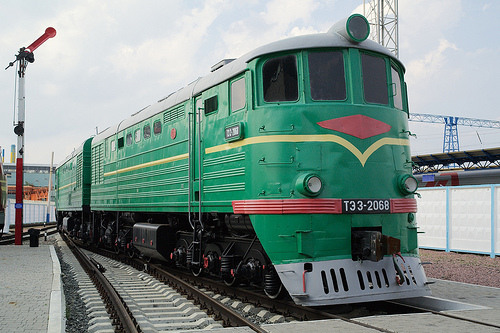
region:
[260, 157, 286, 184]
thetrain is green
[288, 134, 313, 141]
the train is yellow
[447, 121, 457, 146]
the tower is blue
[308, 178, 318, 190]
the light is off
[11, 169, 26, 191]
the pole is red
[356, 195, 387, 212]
the numbers are white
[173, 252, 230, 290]
the train is on the track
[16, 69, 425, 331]
the train is green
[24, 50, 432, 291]
the train is green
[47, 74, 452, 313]
the train is green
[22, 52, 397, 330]
the train is green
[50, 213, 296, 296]
train's wheels are black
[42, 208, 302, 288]
train's wheels are black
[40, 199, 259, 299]
train's wheels are black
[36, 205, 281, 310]
train's wheels are black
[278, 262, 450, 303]
The grill of the train.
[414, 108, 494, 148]
A crane sits in the background.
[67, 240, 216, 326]
An empty rail track.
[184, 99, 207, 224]
The door into the train.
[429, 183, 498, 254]
A wall enclosure.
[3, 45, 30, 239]
A light pole.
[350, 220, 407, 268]
The train spot light.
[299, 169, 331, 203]
right head light of a train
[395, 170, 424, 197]
left head light of a train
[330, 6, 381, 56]
head light on top of a train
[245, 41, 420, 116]
front window of a train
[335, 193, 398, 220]
License plate on front of a train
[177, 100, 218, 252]
Ladder rails on side of train door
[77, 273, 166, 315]
Metal train tracks on gravel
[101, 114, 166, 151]
Windows on the side of a train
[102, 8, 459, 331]
Green train on train tracks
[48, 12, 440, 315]
green passenger train on track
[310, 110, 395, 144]
red spot on front of train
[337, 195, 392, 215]
identification number on front of train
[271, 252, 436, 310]
gray metal grate on train front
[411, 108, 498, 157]
blue construction crane in background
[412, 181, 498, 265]
blue and white divider wall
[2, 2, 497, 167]
fluffy white clouds in sky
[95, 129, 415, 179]
yellow stripe on train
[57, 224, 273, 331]
left side train track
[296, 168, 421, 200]
headlights on front of train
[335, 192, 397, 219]
alpha numeric writing on train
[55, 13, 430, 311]
A green train on the tracks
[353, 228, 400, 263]
A coupler on a train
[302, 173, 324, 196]
A head light on a train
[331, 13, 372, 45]
A light on top of a train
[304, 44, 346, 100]
A window on a train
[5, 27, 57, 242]
A train signal near the tracks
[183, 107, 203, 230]
Hand rails on a train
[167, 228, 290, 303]
Wheels on a train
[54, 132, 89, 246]
A passenger car on the tracks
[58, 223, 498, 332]
Rails on the ground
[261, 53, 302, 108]
A window on a vehicle.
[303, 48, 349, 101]
A window on a vehicle.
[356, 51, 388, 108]
A window on a vehicle.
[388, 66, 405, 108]
A window on a vehicle.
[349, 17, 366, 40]
A window on a vehicle.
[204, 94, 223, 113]
A window on a vehicle.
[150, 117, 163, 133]
A window on a vehicle.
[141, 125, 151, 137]
A window on a vehicle.